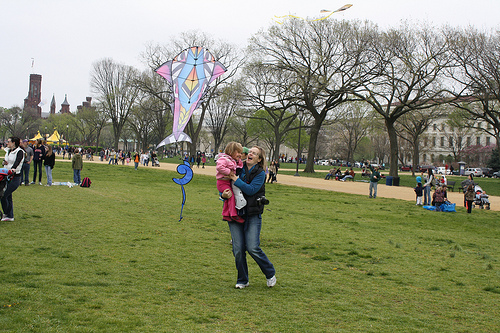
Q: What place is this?
A: It is a field.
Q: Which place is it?
A: It is a field.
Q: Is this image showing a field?
A: Yes, it is showing a field.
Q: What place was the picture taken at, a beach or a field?
A: It was taken at a field.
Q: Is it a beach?
A: No, it is a field.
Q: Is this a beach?
A: No, it is a field.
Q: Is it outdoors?
A: Yes, it is outdoors.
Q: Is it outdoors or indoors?
A: It is outdoors.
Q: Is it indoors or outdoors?
A: It is outdoors.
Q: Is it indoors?
A: No, it is outdoors.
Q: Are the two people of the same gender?
A: Yes, all the people are female.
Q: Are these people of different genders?
A: No, all the people are female.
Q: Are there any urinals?
A: No, there are no urinals.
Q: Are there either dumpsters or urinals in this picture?
A: No, there are no urinals or dumpsters.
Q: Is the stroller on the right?
A: Yes, the stroller is on the right of the image.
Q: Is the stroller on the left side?
A: No, the stroller is on the right of the image.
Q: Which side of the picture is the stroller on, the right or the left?
A: The stroller is on the right of the image.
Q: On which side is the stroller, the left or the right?
A: The stroller is on the right of the image.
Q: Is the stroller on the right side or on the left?
A: The stroller is on the right of the image.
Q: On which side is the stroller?
A: The stroller is on the right of the image.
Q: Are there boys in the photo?
A: No, there are no boys.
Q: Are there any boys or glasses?
A: No, there are no boys or glasses.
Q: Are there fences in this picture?
A: No, there are no fences.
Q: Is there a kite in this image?
A: Yes, there is a kite.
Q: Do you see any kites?
A: Yes, there is a kite.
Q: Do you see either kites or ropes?
A: Yes, there is a kite.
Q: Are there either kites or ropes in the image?
A: Yes, there is a kite.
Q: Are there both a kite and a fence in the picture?
A: No, there is a kite but no fences.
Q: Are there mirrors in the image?
A: No, there are no mirrors.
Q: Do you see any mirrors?
A: No, there are no mirrors.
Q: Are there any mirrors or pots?
A: No, there are no mirrors or pots.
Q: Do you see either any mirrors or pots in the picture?
A: No, there are no mirrors or pots.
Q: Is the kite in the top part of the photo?
A: Yes, the kite is in the top of the image.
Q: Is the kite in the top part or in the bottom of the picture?
A: The kite is in the top of the image.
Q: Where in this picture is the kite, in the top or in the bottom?
A: The kite is in the top of the image.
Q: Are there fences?
A: No, there are no fences.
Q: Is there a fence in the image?
A: No, there are no fences.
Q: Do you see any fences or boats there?
A: No, there are no fences or boats.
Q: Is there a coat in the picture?
A: Yes, there is a coat.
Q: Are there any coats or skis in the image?
A: Yes, there is a coat.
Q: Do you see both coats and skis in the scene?
A: No, there is a coat but no skis.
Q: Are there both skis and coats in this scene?
A: No, there is a coat but no skis.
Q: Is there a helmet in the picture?
A: No, there are no helmets.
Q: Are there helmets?
A: No, there are no helmets.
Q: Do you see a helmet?
A: No, there are no helmets.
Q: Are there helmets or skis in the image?
A: No, there are no helmets or skis.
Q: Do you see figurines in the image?
A: No, there are no figurines.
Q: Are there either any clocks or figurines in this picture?
A: No, there are no figurines or clocks.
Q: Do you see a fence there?
A: No, there are no fences.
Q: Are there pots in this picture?
A: No, there are no pots.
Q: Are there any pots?
A: No, there are no pots.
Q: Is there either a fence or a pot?
A: No, there are no pots or fences.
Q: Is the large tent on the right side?
A: No, the tent is on the left of the image.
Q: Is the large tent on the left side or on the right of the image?
A: The tent is on the left of the image.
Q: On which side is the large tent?
A: The tent is on the left of the image.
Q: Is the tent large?
A: Yes, the tent is large.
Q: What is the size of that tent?
A: The tent is large.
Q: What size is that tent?
A: The tent is large.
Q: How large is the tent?
A: The tent is large.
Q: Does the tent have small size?
A: No, the tent is large.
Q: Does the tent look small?
A: No, the tent is large.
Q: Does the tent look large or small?
A: The tent is large.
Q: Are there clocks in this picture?
A: No, there are no clocks.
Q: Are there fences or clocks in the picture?
A: No, there are no clocks or fences.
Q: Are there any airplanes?
A: No, there are no airplanes.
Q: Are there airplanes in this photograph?
A: No, there are no airplanes.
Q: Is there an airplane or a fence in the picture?
A: No, there are no airplanes or fences.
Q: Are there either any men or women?
A: Yes, there is a woman.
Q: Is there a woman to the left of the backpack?
A: Yes, there is a woman to the left of the backpack.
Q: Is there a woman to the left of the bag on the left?
A: Yes, there is a woman to the left of the backpack.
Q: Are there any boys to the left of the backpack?
A: No, there is a woman to the left of the backpack.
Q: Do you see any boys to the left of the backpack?
A: No, there is a woman to the left of the backpack.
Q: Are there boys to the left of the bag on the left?
A: No, there is a woman to the left of the backpack.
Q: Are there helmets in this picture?
A: No, there are no helmets.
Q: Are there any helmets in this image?
A: No, there are no helmets.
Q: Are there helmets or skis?
A: No, there are no helmets or skis.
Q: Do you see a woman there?
A: Yes, there is a woman.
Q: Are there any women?
A: Yes, there is a woman.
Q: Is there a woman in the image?
A: Yes, there is a woman.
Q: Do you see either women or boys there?
A: Yes, there is a woman.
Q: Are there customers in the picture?
A: No, there are no customers.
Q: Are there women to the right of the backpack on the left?
A: Yes, there is a woman to the right of the backpack.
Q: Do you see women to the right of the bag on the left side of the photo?
A: Yes, there is a woman to the right of the backpack.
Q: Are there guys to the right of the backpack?
A: No, there is a woman to the right of the backpack.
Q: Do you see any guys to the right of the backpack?
A: No, there is a woman to the right of the backpack.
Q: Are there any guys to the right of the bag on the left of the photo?
A: No, there is a woman to the right of the backpack.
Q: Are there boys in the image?
A: No, there are no boys.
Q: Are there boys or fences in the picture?
A: No, there are no boys or fences.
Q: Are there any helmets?
A: No, there are no helmets.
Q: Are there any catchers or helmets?
A: No, there are no helmets or catchers.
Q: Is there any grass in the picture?
A: Yes, there is grass.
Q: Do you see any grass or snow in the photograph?
A: Yes, there is grass.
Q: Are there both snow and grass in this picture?
A: No, there is grass but no snow.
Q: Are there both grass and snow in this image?
A: No, there is grass but no snow.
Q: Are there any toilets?
A: No, there are no toilets.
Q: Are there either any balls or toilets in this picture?
A: No, there are no toilets or balls.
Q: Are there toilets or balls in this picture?
A: No, there are no toilets or balls.